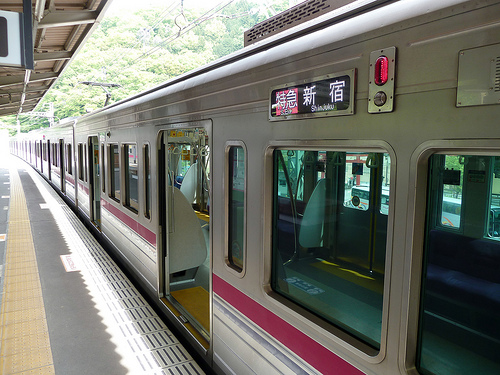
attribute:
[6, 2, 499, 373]
train — long, unmoving, empty, grey, large, parked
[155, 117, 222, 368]
door — open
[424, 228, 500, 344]
seats — blue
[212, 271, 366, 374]
line — red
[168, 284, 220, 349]
doorway — yellow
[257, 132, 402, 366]
windows — empty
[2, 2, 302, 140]
trees — growing, in back, gren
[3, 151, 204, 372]
floor — tiled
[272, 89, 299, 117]
characters — white, japanese, lit up, in chinese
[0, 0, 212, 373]
station — brown, barren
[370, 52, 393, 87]
light — red